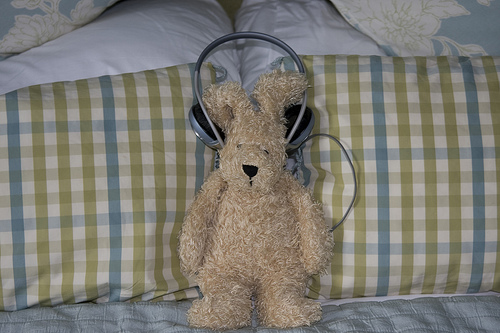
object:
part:
[52, 113, 134, 209]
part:
[362, 198, 465, 293]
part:
[63, 155, 138, 303]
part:
[332, 177, 492, 233]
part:
[32, 174, 105, 317]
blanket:
[0, 302, 168, 333]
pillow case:
[15, 81, 81, 96]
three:
[421, 116, 472, 193]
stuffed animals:
[174, 73, 337, 330]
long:
[372, 258, 432, 297]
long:
[40, 198, 109, 307]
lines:
[288, 133, 357, 233]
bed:
[0, 0, 499, 333]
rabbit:
[175, 68, 334, 332]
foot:
[184, 296, 255, 331]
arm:
[175, 168, 226, 253]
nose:
[240, 163, 258, 178]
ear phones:
[187, 30, 316, 150]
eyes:
[236, 144, 269, 155]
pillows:
[1, 55, 500, 312]